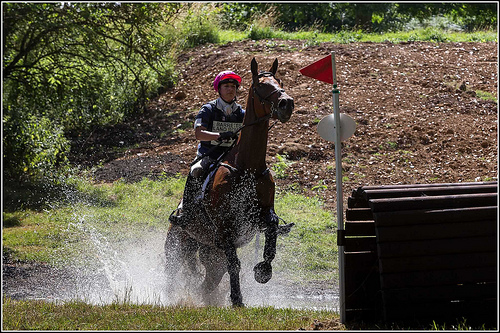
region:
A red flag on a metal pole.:
[297, 36, 355, 114]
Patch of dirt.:
[364, 61, 471, 176]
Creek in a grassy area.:
[0, 272, 333, 314]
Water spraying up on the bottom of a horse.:
[90, 202, 289, 295]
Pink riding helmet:
[201, 60, 256, 110]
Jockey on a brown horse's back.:
[150, 54, 300, 269]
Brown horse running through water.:
[115, 53, 322, 331]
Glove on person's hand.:
[210, 122, 242, 149]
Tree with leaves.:
[0, 0, 167, 217]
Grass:
[10, 302, 325, 327]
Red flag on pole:
[289, 45, 373, 115]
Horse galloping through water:
[140, 36, 321, 328]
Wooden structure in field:
[341, 182, 498, 328]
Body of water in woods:
[42, 240, 345, 329]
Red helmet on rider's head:
[194, 62, 253, 94]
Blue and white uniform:
[186, 98, 243, 167]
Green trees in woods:
[5, 0, 177, 192]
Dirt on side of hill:
[357, 30, 492, 166]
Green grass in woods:
[6, 182, 159, 245]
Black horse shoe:
[245, 255, 285, 293]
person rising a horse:
[143, 51, 305, 311]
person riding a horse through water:
[155, 42, 304, 313]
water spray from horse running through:
[57, 217, 181, 307]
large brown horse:
[155, 57, 307, 309]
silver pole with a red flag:
[300, 38, 353, 323]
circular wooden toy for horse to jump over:
[326, 176, 496, 327]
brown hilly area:
[291, 37, 485, 184]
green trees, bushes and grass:
[15, 8, 161, 181]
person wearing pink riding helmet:
[198, 66, 246, 97]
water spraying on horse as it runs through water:
[205, 168, 262, 253]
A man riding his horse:
[144, 49, 319, 319]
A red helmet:
[196, 43, 247, 99]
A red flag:
[289, 36, 354, 96]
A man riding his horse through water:
[16, 27, 481, 327]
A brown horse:
[156, 56, 318, 328]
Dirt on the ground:
[364, 51, 491, 173]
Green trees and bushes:
[5, 0, 205, 207]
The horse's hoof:
[243, 243, 290, 289]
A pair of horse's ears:
[226, 37, 291, 83]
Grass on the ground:
[9, 176, 367, 331]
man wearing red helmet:
[210, 65, 243, 90]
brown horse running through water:
[163, 57, 299, 309]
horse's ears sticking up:
[247, 52, 279, 76]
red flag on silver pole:
[298, 52, 333, 88]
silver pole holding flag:
[329, 86, 346, 320]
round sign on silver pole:
[317, 111, 356, 141]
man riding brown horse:
[181, 70, 246, 220]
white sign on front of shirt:
[211, 118, 243, 145]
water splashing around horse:
[23, 121, 296, 309]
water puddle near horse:
[14, 265, 341, 311]